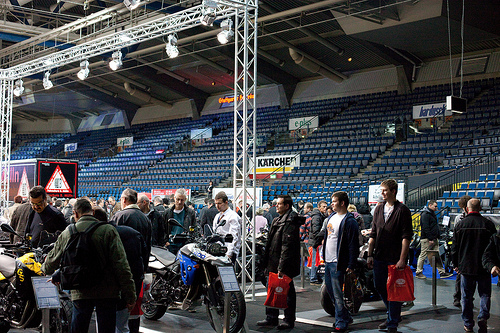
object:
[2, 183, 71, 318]
people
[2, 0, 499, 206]
arena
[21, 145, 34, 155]
terraces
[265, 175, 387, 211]
stand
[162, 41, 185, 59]
light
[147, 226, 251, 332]
bike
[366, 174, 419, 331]
man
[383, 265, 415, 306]
bag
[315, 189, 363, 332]
man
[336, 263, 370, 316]
bag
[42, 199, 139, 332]
person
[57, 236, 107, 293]
backpack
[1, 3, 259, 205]
structure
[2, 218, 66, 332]
motorcycle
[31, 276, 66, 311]
sign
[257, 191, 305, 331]
man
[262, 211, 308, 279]
jacket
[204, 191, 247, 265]
man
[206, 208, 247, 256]
jacket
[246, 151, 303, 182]
sign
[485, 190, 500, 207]
seat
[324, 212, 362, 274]
sweater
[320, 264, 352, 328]
jeans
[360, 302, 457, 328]
shadow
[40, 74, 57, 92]
light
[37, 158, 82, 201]
sign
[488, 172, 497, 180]
seat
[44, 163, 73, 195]
triangle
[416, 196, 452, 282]
man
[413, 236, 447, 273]
khakis